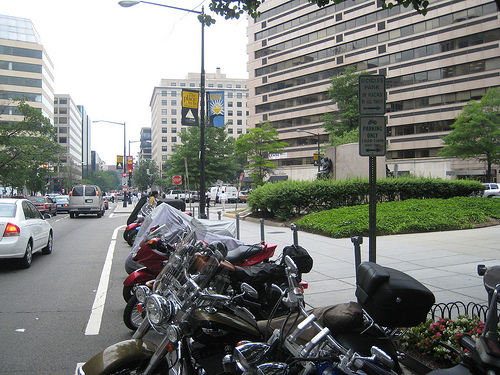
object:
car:
[0, 198, 54, 267]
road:
[0, 196, 139, 371]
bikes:
[217, 254, 499, 374]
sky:
[5, 0, 244, 133]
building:
[245, 0, 498, 184]